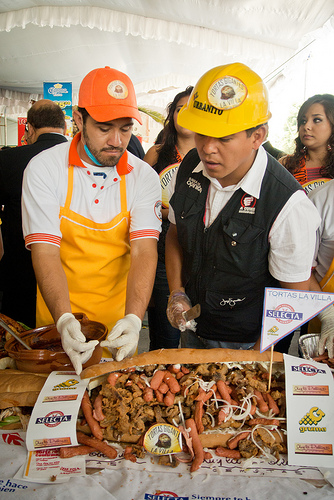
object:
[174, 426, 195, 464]
pepper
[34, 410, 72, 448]
label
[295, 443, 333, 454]
tag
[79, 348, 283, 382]
half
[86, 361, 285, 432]
inside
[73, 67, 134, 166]
head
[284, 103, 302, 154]
something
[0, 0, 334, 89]
ceiling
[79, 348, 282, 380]
brown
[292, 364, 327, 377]
design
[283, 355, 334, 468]
paper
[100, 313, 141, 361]
gloves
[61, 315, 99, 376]
hand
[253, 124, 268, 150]
ear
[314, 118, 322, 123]
eyes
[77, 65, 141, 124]
orange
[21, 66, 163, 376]
man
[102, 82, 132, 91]
logo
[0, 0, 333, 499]
photo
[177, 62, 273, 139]
hat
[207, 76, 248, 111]
sticker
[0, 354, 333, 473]
food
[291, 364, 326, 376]
writing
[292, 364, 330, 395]
paper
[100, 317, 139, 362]
hands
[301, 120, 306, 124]
eyes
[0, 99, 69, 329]
man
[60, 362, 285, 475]
sub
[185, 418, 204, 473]
hot dog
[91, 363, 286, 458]
beef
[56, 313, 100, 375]
gloves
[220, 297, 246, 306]
signature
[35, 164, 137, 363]
apron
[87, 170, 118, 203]
button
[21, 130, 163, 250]
shirt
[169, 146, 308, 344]
vest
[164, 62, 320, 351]
man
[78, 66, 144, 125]
cap